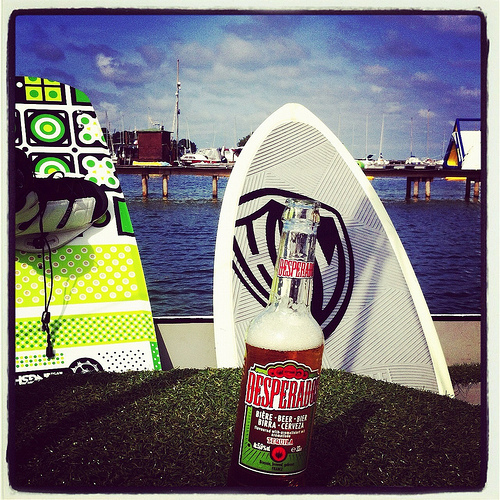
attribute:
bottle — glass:
[213, 190, 326, 487]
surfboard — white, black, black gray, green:
[199, 88, 462, 404]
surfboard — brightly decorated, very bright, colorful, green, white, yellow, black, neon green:
[13, 65, 162, 372]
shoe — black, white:
[12, 143, 110, 237]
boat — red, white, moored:
[179, 149, 228, 169]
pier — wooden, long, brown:
[105, 158, 480, 210]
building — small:
[133, 128, 173, 166]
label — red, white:
[241, 368, 319, 413]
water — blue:
[107, 164, 480, 321]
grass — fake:
[11, 362, 491, 493]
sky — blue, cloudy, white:
[16, 16, 483, 164]